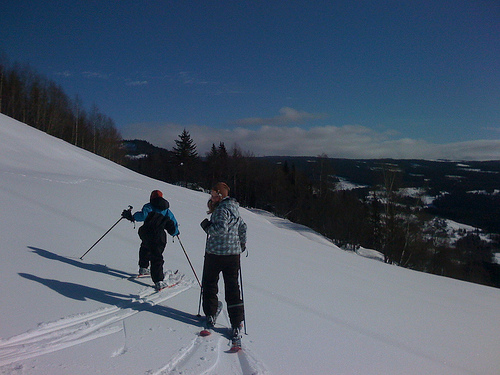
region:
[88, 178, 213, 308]
the kid is skiing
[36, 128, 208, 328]
the kid is skiing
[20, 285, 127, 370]
ski prints on the snow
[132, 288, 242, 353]
ski prints on the snow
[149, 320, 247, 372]
ski prints on the snow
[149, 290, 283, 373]
ski prints on the snow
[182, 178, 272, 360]
girl looking to her side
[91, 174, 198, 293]
small boy skiing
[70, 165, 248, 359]
two people on snow together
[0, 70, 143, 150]
small forest in back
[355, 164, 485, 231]
mountains in the distance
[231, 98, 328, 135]
cloud in the sky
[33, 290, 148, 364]
ski trail in the snow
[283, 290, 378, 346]
snow untouched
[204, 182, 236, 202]
brown hat on girl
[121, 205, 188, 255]
black and blue jacket on boy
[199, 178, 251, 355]
Skier on mountain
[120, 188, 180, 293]
Skier on mountain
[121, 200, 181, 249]
Blue and black jacket on skier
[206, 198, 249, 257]
Flannel shirt on skier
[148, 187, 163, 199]
Orange hat on skier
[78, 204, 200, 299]
Poles of skier with blue and black jacket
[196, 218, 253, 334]
Poles of skier with plaid jacket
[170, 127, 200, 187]
Big pine tree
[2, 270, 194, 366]
Ski trial in the white snow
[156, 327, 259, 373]
Ski trail in the white snow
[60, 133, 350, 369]
people skiing on the snow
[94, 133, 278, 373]
two people skiing in the snow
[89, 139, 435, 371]
two people on skies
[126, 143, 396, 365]
two people standing on skies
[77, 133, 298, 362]
people standing on skies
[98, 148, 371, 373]
two people holding ski poles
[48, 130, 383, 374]
poeople holding ski poles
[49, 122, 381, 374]
a ground covered in snow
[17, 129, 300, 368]
a ground covered in white snow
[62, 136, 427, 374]
snow covere the ground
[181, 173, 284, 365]
the girl looking at her back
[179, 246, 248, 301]
the pants are black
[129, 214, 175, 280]
the pants are black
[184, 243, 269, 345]
the pants are black